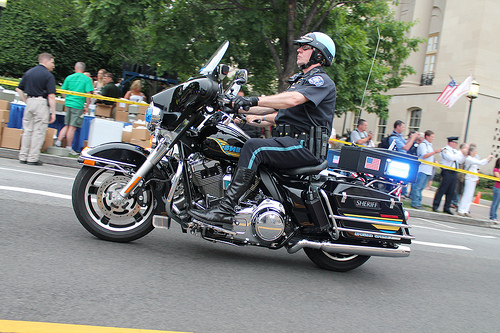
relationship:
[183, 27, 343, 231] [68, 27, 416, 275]
officer riding motorcycle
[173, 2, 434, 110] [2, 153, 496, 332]
tree near street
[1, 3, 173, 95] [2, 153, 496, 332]
tree near street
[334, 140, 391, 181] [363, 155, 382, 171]
garbage can has american flag decal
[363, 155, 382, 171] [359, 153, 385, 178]
american flag decal of american flag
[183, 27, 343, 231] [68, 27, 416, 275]
officer has motorcycle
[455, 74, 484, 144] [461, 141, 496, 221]
street light above person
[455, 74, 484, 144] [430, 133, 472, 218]
street light above person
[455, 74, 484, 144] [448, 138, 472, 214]
street light above person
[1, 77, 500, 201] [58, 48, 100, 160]
tape keeps back person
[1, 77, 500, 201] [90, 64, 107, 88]
tape keeps back person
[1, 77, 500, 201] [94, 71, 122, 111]
tape keeps back person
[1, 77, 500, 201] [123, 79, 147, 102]
tape keeps back woman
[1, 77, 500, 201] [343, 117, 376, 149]
tape keeps back person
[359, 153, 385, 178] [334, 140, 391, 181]
american flag on garbage can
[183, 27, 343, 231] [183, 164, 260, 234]
officer wearing boot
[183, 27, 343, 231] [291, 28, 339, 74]
officer wearing helmet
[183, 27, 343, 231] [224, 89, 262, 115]
officer wearing glove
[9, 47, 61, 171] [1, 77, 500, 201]
man standing by tape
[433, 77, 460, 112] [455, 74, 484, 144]
american flag near street light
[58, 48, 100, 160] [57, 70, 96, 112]
person wearing shirt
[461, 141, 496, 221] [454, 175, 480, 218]
person in pants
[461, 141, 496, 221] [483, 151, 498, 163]
person holding camera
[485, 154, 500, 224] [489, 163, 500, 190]
person wearing top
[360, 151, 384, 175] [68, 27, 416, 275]
american flag decal on motorcycle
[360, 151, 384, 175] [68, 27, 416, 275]
american flag decal on back of motorcycle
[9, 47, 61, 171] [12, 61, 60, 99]
man in shirt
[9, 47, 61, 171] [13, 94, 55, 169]
man in pants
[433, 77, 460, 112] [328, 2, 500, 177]
american flag on side of building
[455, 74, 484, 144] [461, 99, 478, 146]
street light has post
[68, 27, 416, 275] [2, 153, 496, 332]
motorcycle on street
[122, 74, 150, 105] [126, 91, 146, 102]
woman in tank top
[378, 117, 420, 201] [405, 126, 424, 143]
person taking picture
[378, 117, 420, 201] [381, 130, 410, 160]
person in shirt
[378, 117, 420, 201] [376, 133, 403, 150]
person has backpack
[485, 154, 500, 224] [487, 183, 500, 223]
person in jeans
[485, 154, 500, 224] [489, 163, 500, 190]
person in top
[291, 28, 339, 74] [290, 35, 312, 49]
helmet has part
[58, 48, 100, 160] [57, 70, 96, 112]
person in shirt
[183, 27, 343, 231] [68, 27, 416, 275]
officer on motorcycle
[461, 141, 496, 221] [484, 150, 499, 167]
person taking picture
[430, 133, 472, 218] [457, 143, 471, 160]
person taking picture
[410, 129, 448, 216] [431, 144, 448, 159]
person taking picture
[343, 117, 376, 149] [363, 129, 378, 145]
person taking picture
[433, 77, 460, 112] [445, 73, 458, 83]
american flag on pole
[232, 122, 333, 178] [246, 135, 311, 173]
pants have strip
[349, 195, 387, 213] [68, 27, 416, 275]
word on motorcycle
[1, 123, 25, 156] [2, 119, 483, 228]
box on sidewalk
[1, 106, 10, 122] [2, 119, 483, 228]
box on sidewalk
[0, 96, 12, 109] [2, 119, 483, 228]
box on sidewalk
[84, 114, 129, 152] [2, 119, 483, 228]
box on sidewalk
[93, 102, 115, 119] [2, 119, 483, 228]
box on sidewalk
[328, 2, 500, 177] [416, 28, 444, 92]
building has window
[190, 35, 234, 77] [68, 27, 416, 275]
windshied on motorcycle